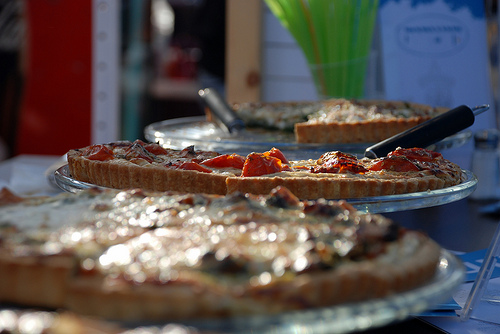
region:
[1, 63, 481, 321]
three pies on a table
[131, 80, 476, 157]
three quarters of a pie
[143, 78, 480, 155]
pie is over a big plate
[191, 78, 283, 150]
a spatula ona plate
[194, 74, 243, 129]
handle of spatula is black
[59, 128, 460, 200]
the pie height is short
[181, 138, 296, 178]
strawberry ona pie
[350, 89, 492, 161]
handle of a spatula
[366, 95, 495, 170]
handle of spatula is black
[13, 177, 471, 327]
pie on a silver plate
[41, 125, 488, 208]
tart of cream and strawberry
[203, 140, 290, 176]
pieces of red strawberries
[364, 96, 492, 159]
handle of a spatule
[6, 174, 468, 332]
tart of cream an fruits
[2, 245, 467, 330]
plate holding a tart is silver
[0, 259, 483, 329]
the silver plate is big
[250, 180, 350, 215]
purple berries in pie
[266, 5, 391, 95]
a green curtain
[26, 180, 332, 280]
center of pie is shining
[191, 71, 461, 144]
a slice of pie is missing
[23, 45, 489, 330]
three pizzas in a row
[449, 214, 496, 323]
a blue table top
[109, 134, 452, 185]
toasted pepperoni on a pizza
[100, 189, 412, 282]
brown meat on a pizza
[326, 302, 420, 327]
a glass pedestal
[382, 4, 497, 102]
a blue and white sign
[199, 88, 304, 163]
a pizza server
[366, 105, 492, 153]
a long black handle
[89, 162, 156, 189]
a brown scalloped pizza crust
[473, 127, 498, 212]
a filled salt shaker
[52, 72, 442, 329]
three pizzas on a table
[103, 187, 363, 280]
cheese and meat on a pizza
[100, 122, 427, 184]
pepperoni and cheese on a pizza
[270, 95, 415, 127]
white cheese on a pizza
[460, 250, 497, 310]
blue paper on a table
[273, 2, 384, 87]
a green vase behind the pizzas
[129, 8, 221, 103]
a doorway in the background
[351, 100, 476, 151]
the black handle on a server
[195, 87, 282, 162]
a pizza server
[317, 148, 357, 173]
a charred piece of pepperoni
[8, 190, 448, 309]
A whole pizza pie.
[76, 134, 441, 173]
Tomatoes on the pizza.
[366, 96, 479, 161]
The handle of a spatula.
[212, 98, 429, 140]
A pizza and a scooper.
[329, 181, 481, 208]
A tray for the pizza.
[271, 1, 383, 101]
A tall green plant.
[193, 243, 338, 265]
Meat on the pizza.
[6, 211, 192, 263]
The dough covered in cheese.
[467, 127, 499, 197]
salt.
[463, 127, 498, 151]
The lid of the salt container.